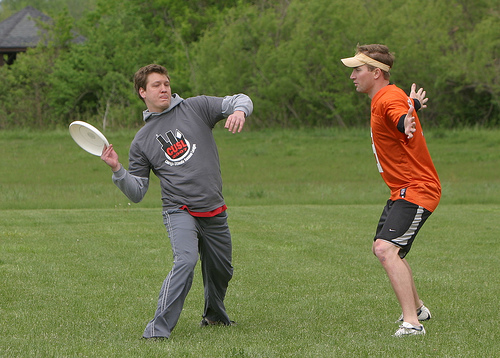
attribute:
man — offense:
[94, 57, 267, 344]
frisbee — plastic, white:
[66, 112, 110, 161]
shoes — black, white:
[387, 301, 436, 342]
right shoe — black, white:
[403, 304, 433, 323]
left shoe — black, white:
[388, 317, 431, 340]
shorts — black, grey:
[368, 196, 435, 255]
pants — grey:
[142, 206, 237, 343]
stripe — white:
[161, 210, 179, 326]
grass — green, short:
[0, 124, 500, 356]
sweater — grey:
[110, 91, 257, 206]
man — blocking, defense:
[336, 40, 444, 343]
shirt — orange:
[362, 82, 446, 216]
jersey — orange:
[365, 81, 446, 213]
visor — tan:
[337, 48, 394, 77]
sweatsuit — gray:
[110, 88, 259, 339]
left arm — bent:
[191, 91, 256, 136]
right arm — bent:
[119, 137, 154, 208]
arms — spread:
[380, 70, 434, 138]